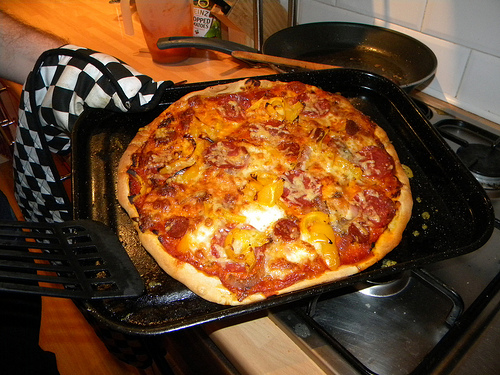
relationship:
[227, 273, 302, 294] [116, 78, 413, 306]
tomato sauce on pizza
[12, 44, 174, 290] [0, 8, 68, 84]
oven mitt on arm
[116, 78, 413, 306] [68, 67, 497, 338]
pizza on pan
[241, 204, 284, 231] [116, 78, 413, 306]
cheese on pizza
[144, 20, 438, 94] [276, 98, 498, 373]
frying pan on oven top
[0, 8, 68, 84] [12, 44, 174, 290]
arm wearing oven mitt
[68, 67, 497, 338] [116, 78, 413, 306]
pan under pizza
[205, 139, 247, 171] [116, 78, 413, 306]
pepperoni on pizza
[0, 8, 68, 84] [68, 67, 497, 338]
arm holding pan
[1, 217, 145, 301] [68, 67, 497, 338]
spatula on pan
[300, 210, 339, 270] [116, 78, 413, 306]
peppers on pizza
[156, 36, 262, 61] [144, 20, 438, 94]
handle on frying pan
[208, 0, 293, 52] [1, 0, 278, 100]
knife block on counter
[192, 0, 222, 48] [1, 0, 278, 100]
bottle on counter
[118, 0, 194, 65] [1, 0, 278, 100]
pitcher on counter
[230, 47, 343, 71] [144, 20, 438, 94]
utensil in frying pan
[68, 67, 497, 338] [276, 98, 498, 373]
pan on oven top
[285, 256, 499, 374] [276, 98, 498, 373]
burner on oven top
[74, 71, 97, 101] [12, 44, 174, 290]
square on oven mitt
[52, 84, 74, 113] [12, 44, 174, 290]
square on oven mitt